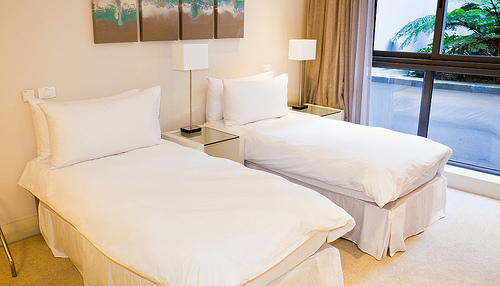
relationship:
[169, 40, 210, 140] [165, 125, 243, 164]
lamp on a night stand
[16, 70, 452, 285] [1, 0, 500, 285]
two beds are in hotel room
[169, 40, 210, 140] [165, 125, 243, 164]
lamp resting on night stand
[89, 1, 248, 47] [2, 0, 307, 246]
four paintings are on wall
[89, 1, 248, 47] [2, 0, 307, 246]
paintings are on wall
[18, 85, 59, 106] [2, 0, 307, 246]
lighting controls are on wall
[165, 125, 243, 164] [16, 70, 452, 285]
night stand between two beds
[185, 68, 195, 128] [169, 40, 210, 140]
metal pole on lamp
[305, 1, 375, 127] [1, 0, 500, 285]
curtains are in hotel room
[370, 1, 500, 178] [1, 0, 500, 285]
window in hotel room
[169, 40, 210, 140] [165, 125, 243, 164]
lamp on night stand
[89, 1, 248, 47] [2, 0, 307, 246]
four pictures are hanging on wall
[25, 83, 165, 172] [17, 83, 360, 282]
pillows are lying on bed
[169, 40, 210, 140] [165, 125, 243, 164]
lamp sitting on night stand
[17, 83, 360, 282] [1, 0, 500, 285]
bed in hotel room